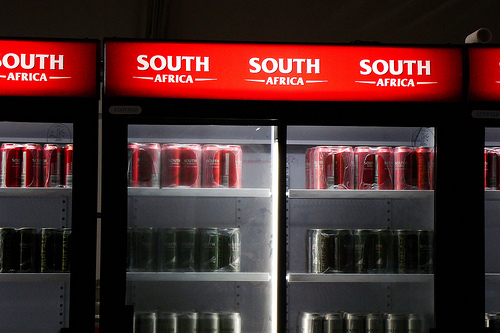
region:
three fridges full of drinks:
[6, 31, 492, 331]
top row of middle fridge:
[127, 128, 427, 191]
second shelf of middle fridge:
[123, 202, 432, 274]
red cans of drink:
[4, 125, 493, 190]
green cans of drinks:
[0, 209, 432, 276]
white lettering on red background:
[2, 40, 450, 97]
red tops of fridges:
[5, 40, 489, 97]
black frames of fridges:
[10, 94, 496, 320]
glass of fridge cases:
[8, 117, 490, 329]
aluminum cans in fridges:
[2, 124, 499, 332]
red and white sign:
[111, 40, 451, 91]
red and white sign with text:
[108, 40, 448, 95]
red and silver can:
[201, 141, 221, 183]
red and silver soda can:
[201, 142, 221, 183]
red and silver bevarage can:
[200, 140, 220, 186]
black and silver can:
[307, 225, 335, 271]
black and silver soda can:
[310, 226, 338, 271]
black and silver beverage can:
[310, 227, 335, 272]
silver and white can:
[222, 311, 237, 329]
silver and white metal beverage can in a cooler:
[222, 312, 239, 332]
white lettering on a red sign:
[126, 52, 215, 89]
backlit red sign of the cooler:
[114, 51, 439, 98]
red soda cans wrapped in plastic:
[131, 143, 248, 185]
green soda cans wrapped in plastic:
[132, 226, 242, 270]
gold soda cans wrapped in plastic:
[136, 306, 247, 331]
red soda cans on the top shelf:
[310, 148, 430, 195]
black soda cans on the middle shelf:
[307, 226, 430, 273]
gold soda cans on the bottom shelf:
[298, 305, 422, 332]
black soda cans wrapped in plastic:
[299, 227, 435, 276]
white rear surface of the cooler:
[251, 210, 270, 267]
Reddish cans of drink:
[164, 150, 194, 178]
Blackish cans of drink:
[339, 238, 370, 255]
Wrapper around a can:
[205, 150, 210, 186]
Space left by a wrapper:
[368, 160, 375, 182]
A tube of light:
[273, 145, 276, 252]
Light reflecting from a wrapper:
[232, 231, 239, 267]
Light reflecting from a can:
[301, 318, 312, 332]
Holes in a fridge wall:
[57, 283, 64, 324]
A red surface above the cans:
[218, 58, 237, 89]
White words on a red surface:
[135, 54, 212, 71]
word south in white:
[250, 58, 332, 75]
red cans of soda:
[306, 146, 428, 186]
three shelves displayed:
[279, 148, 434, 331]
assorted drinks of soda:
[5, 144, 431, 331]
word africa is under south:
[372, 77, 428, 92]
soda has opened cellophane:
[354, 147, 393, 200]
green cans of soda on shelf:
[130, 228, 430, 268]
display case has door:
[107, 96, 469, 317]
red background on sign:
[0, 43, 496, 94]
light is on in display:
[132, 126, 427, 326]